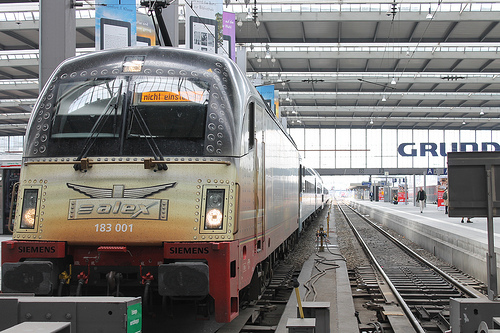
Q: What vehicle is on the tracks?
A: TRain.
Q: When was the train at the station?
A: During daylight hours.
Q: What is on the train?
A: Front headlight.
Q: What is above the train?
A: A roof.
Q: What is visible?
A: A roof.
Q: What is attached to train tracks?
A: A metal plate.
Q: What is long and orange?
A: A train.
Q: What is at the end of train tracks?
A: Metal structure.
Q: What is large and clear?
A: Windows.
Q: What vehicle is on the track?
A: Train.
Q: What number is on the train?
A: 183 001.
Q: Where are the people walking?
A: On the platform.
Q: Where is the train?
A: On the tracks.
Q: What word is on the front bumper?
A: Siemens.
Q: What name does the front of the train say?
A: Alex.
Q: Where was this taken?
A: A train station.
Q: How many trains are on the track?
A: One.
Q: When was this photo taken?
A: During the day.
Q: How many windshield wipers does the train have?
A: Two.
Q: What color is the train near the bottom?
A: Red.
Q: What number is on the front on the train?
A: 183001.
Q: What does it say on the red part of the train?
A: Siemens.